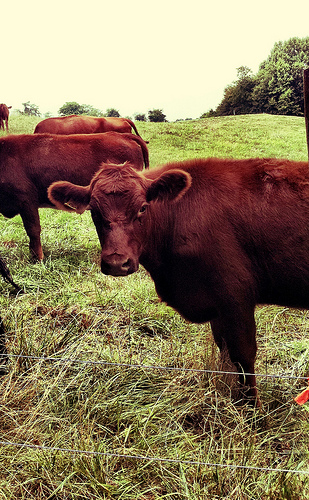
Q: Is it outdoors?
A: Yes, it is outdoors.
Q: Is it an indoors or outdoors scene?
A: It is outdoors.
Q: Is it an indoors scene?
A: No, it is outdoors.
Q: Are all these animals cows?
A: Yes, all the animals are cows.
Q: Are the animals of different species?
A: No, all the animals are cows.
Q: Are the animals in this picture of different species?
A: No, all the animals are cows.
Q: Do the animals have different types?
A: No, all the animals are cows.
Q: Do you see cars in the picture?
A: No, there are no cars.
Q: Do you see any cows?
A: Yes, there is a cow.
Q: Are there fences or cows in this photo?
A: Yes, there is a cow.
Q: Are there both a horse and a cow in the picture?
A: No, there is a cow but no horses.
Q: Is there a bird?
A: No, there are no birds.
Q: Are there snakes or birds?
A: No, there are no birds or snakes.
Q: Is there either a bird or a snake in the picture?
A: No, there are no birds or snakes.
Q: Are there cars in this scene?
A: No, there are no cars.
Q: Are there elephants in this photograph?
A: No, there are no elephants.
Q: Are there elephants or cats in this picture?
A: No, there are no elephants or cats.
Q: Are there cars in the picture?
A: No, there are no cars.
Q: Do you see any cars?
A: No, there are no cars.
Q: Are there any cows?
A: Yes, there is a cow.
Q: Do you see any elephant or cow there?
A: Yes, there is a cow.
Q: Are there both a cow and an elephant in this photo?
A: No, there is a cow but no elephants.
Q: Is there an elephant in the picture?
A: No, there are no elephants.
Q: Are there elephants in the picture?
A: No, there are no elephants.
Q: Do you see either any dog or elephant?
A: No, there are no elephants or dogs.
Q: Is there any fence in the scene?
A: Yes, there is a fence.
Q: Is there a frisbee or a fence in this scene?
A: Yes, there is a fence.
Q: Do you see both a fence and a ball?
A: No, there is a fence but no balls.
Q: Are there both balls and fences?
A: No, there is a fence but no balls.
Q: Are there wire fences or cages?
A: Yes, there is a wire fence.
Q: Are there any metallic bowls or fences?
A: Yes, there is a metal fence.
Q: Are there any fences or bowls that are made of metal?
A: Yes, the fence is made of metal.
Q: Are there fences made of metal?
A: Yes, there is a fence that is made of metal.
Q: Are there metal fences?
A: Yes, there is a fence that is made of metal.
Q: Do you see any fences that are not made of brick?
A: Yes, there is a fence that is made of metal.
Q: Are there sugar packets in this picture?
A: No, there are no sugar packets.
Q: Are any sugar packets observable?
A: No, there are no sugar packets.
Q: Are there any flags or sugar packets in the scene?
A: No, there are no sugar packets or flags.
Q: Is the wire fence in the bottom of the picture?
A: Yes, the fence is in the bottom of the image.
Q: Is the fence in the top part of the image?
A: No, the fence is in the bottom of the image.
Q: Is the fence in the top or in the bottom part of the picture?
A: The fence is in the bottom of the image.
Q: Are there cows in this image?
A: Yes, there is a cow.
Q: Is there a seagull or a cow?
A: Yes, there is a cow.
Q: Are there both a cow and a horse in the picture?
A: No, there is a cow but no horses.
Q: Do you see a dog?
A: No, there are no dogs.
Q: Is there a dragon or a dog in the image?
A: No, there are no dogs or dragons.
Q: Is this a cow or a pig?
A: This is a cow.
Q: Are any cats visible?
A: No, there are no cats.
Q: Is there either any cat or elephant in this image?
A: No, there are no cats or elephants.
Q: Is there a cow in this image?
A: Yes, there is a cow.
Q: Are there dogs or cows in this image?
A: Yes, there is a cow.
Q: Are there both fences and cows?
A: Yes, there are both a cow and a fence.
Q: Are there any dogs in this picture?
A: No, there are no dogs.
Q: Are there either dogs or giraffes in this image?
A: No, there are no dogs or giraffes.